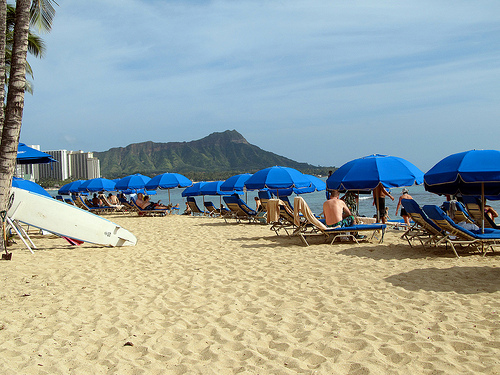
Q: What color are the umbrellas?
A: Blue.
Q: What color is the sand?
A: Brown.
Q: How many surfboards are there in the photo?
A: One.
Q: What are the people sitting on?
A: Lounge chairs.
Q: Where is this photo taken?
A: On a beach.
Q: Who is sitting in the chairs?
A: Men and women.